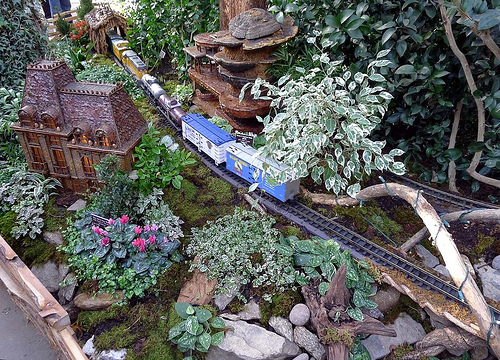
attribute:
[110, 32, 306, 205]
train — toy, long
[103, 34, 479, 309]
train tracks — black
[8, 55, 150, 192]
building — brown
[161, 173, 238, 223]
moss — growing, green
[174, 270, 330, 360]
rocks — gray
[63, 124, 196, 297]
plants — green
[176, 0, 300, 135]
wood — brown, gray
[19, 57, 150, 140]
roof — tall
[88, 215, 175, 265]
flowers — purple, pink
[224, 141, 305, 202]
train car — blue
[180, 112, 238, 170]
train car — white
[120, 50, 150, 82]
train car — yellow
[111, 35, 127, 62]
train car — yellow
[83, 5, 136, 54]
tunnel — brown, old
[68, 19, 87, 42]
flowers — orange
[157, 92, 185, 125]
train car — maroon